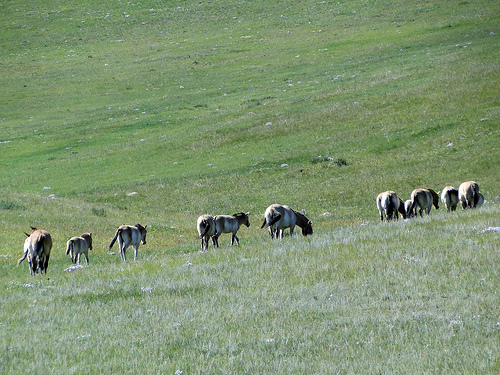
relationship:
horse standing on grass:
[377, 189, 397, 220] [1, 2, 496, 374]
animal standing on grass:
[458, 181, 480, 210] [1, 2, 496, 374]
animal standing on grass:
[110, 223, 149, 261] [1, 2, 496, 374]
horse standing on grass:
[265, 204, 310, 239] [1, 2, 496, 374]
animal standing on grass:
[210, 212, 250, 248] [1, 2, 496, 374]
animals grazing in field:
[65, 233, 93, 266] [1, 2, 498, 373]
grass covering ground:
[1, 2, 496, 374] [1, 0, 496, 372]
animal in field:
[110, 223, 149, 261] [1, 2, 498, 373]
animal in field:
[196, 214, 216, 249] [1, 2, 498, 373]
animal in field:
[210, 210, 251, 247] [1, 2, 498, 373]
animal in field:
[261, 204, 314, 241] [1, 2, 498, 373]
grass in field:
[1, 0, 500, 375] [2, 24, 492, 356]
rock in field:
[264, 121, 271, 127] [1, 2, 498, 373]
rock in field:
[446, 141, 455, 147] [1, 2, 498, 373]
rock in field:
[278, 162, 287, 168] [1, 2, 498, 373]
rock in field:
[126, 191, 139, 197] [1, 2, 498, 373]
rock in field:
[178, 85, 184, 90] [1, 2, 498, 373]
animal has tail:
[120, 218, 145, 265] [107, 228, 119, 249]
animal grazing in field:
[110, 223, 149, 261] [18, 201, 496, 367]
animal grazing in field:
[197, 214, 218, 251] [1, 2, 498, 373]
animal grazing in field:
[210, 212, 250, 248] [1, 2, 498, 373]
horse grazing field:
[387, 140, 458, 245] [170, 47, 462, 294]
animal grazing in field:
[441, 185, 459, 212] [1, 2, 498, 373]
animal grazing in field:
[458, 181, 480, 210] [185, 188, 498, 371]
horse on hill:
[128, 178, 263, 258] [25, 11, 390, 345]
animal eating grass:
[261, 204, 314, 241] [95, 99, 426, 357]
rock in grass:
[124, 187, 142, 197] [1, 2, 496, 374]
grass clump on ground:
[330, 152, 352, 169] [1, 0, 496, 372]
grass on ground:
[1, 2, 496, 374] [1, 0, 496, 372]